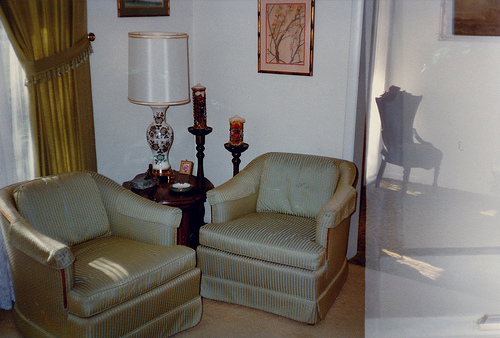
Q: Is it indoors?
A: Yes, it is indoors.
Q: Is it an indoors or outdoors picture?
A: It is indoors.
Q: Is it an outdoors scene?
A: No, it is indoors.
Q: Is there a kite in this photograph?
A: No, there are no kites.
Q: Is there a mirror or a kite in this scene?
A: No, there are no kites or mirrors.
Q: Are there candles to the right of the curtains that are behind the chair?
A: Yes, there is a candle to the right of the curtains.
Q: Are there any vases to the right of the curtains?
A: No, there is a candle to the right of the curtains.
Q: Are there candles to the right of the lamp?
A: Yes, there is a candle to the right of the lamp.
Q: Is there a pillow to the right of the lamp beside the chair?
A: No, there is a candle to the right of the lamp.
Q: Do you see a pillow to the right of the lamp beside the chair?
A: No, there is a candle to the right of the lamp.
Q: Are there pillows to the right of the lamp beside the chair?
A: No, there is a candle to the right of the lamp.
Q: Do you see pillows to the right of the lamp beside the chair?
A: No, there is a candle to the right of the lamp.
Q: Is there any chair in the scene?
A: Yes, there is a chair.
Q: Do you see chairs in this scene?
A: Yes, there is a chair.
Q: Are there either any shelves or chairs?
A: Yes, there is a chair.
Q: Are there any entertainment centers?
A: No, there are no entertainment centers.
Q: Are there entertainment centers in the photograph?
A: No, there are no entertainment centers.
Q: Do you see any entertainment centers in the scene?
A: No, there are no entertainment centers.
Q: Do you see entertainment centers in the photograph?
A: No, there are no entertainment centers.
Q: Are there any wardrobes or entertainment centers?
A: No, there are no entertainment centers or wardrobes.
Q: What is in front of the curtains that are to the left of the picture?
A: The chair is in front of the curtains.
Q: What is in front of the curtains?
A: The chair is in front of the curtains.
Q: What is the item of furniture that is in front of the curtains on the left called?
A: The piece of furniture is a chair.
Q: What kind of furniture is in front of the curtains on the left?
A: The piece of furniture is a chair.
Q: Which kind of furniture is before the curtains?
A: The piece of furniture is a chair.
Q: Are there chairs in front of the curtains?
A: Yes, there is a chair in front of the curtains.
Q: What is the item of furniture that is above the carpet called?
A: The piece of furniture is a chair.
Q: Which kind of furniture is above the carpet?
A: The piece of furniture is a chair.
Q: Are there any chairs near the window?
A: Yes, there is a chair near the window.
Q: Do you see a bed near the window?
A: No, there is a chair near the window.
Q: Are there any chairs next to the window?
A: Yes, there is a chair next to the window.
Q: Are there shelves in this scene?
A: No, there are no shelves.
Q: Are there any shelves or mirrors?
A: No, there are no shelves or mirrors.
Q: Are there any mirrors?
A: No, there are no mirrors.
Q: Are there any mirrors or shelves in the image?
A: No, there are no mirrors or shelves.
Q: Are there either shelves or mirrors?
A: No, there are no mirrors or shelves.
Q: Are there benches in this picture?
A: No, there are no benches.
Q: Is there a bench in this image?
A: No, there are no benches.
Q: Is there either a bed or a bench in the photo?
A: No, there are no benches or beds.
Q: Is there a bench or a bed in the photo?
A: No, there are no benches or beds.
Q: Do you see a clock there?
A: No, there are no clocks.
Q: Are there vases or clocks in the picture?
A: No, there are no clocks or vases.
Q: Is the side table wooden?
A: Yes, the side table is wooden.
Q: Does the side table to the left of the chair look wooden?
A: Yes, the side table is wooden.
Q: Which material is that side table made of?
A: The side table is made of wood.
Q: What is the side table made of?
A: The side table is made of wood.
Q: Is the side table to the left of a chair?
A: Yes, the side table is to the left of a chair.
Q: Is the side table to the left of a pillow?
A: No, the side table is to the left of a chair.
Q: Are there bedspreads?
A: No, there are no bedspreads.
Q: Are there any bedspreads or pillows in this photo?
A: No, there are no bedspreads or pillows.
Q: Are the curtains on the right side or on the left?
A: The curtains are on the left of the image.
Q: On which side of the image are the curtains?
A: The curtains are on the left of the image.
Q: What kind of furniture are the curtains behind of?
A: The curtains are behind the chair.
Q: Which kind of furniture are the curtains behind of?
A: The curtains are behind the chair.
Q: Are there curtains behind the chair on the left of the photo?
A: Yes, there are curtains behind the chair.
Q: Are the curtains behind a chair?
A: Yes, the curtains are behind a chair.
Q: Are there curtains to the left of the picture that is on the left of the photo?
A: Yes, there are curtains to the left of the picture.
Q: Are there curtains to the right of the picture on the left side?
A: No, the curtains are to the left of the picture.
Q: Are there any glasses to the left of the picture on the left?
A: No, there are curtains to the left of the picture.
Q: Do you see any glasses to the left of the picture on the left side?
A: No, there are curtains to the left of the picture.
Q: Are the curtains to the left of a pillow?
A: No, the curtains are to the left of the picture.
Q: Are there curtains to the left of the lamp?
A: Yes, there are curtains to the left of the lamp.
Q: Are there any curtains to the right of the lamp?
A: No, the curtains are to the left of the lamp.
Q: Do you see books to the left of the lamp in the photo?
A: No, there are curtains to the left of the lamp.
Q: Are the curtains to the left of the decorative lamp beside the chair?
A: Yes, the curtains are to the left of the lamp.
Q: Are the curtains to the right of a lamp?
A: No, the curtains are to the left of a lamp.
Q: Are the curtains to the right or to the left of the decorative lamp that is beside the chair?
A: The curtains are to the left of the lamp.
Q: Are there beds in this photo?
A: No, there are no beds.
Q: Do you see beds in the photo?
A: No, there are no beds.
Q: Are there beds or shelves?
A: No, there are no beds or shelves.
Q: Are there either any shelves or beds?
A: No, there are no beds or shelves.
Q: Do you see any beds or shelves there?
A: No, there are no beds or shelves.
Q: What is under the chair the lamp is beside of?
A: The carpet is under the chair.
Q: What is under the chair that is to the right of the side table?
A: The carpet is under the chair.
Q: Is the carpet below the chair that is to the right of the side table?
A: Yes, the carpet is below the chair.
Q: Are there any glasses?
A: No, there are no glasses.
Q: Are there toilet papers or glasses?
A: No, there are no glasses or toilet papers.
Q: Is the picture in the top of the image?
A: Yes, the picture is in the top of the image.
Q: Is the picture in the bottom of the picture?
A: No, the picture is in the top of the image.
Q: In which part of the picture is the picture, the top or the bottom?
A: The picture is in the top of the image.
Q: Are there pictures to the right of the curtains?
A: Yes, there is a picture to the right of the curtains.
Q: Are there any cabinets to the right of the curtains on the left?
A: No, there is a picture to the right of the curtains.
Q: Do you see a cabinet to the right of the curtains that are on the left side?
A: No, there is a picture to the right of the curtains.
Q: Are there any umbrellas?
A: No, there are no umbrellas.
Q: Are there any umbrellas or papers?
A: No, there are no umbrellas or papers.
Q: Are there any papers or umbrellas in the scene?
A: No, there are no umbrellas or papers.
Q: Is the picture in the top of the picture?
A: Yes, the picture is in the top of the image.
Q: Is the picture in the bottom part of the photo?
A: No, the picture is in the top of the image.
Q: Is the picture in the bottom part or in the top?
A: The picture is in the top of the image.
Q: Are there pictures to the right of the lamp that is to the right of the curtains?
A: Yes, there is a picture to the right of the lamp.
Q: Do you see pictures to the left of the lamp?
A: No, the picture is to the right of the lamp.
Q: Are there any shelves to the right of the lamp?
A: No, there is a picture to the right of the lamp.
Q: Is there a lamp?
A: Yes, there is a lamp.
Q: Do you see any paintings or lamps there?
A: Yes, there is a lamp.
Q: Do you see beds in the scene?
A: No, there are no beds.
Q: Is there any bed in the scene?
A: No, there are no beds.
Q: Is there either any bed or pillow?
A: No, there are no beds or pillows.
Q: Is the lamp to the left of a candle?
A: Yes, the lamp is to the left of a candle.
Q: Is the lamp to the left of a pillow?
A: No, the lamp is to the left of a candle.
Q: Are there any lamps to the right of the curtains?
A: Yes, there is a lamp to the right of the curtains.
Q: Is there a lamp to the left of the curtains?
A: No, the lamp is to the right of the curtains.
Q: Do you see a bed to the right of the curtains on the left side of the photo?
A: No, there is a lamp to the right of the curtains.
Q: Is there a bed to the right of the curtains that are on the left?
A: No, there is a lamp to the right of the curtains.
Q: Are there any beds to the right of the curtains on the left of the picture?
A: No, there is a lamp to the right of the curtains.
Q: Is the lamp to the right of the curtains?
A: Yes, the lamp is to the right of the curtains.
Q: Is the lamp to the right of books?
A: No, the lamp is to the right of the curtains.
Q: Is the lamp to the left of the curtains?
A: No, the lamp is to the right of the curtains.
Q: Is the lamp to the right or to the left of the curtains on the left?
A: The lamp is to the right of the curtains.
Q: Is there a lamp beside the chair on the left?
A: Yes, there is a lamp beside the chair.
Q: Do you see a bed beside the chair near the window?
A: No, there is a lamp beside the chair.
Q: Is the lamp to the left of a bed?
A: No, the lamp is to the left of a candle.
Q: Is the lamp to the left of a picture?
A: Yes, the lamp is to the left of a picture.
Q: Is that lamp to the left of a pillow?
A: No, the lamp is to the left of a picture.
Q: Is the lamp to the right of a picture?
A: No, the lamp is to the left of a picture.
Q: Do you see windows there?
A: Yes, there is a window.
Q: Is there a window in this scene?
A: Yes, there is a window.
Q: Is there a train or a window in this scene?
A: Yes, there is a window.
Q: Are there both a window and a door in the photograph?
A: No, there is a window but no doors.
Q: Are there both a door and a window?
A: No, there is a window but no doors.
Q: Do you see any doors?
A: No, there are no doors.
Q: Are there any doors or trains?
A: No, there are no doors or trains.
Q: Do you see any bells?
A: No, there are no bells.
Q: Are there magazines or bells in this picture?
A: No, there are no bells or magazines.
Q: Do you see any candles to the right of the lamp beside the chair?
A: Yes, there is a candle to the right of the lamp.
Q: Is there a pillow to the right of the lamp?
A: No, there is a candle to the right of the lamp.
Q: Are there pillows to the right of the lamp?
A: No, there is a candle to the right of the lamp.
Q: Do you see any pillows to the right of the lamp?
A: No, there is a candle to the right of the lamp.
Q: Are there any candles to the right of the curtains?
A: Yes, there is a candle to the right of the curtains.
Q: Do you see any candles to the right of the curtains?
A: Yes, there is a candle to the right of the curtains.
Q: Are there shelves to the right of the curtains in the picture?
A: No, there is a candle to the right of the curtains.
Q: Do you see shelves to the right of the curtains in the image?
A: No, there is a candle to the right of the curtains.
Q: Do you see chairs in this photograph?
A: Yes, there is a chair.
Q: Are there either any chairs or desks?
A: Yes, there is a chair.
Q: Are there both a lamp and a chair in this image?
A: Yes, there are both a chair and a lamp.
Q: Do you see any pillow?
A: No, there are no pillows.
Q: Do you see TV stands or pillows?
A: No, there are no pillows or TV stands.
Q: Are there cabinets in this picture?
A: No, there are no cabinets.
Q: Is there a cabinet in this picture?
A: No, there are no cabinets.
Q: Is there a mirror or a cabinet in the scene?
A: No, there are no cabinets or mirrors.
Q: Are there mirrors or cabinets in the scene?
A: No, there are no cabinets or mirrors.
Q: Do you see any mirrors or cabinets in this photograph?
A: No, there are no cabinets or mirrors.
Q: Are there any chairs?
A: Yes, there is a chair.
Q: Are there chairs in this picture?
A: Yes, there is a chair.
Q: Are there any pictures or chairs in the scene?
A: Yes, there is a chair.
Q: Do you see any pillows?
A: No, there are no pillows.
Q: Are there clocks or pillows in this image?
A: No, there are no pillows or clocks.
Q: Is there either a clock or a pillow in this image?
A: No, there are no pillows or clocks.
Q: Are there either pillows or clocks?
A: No, there are no pillows or clocks.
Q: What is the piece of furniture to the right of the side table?
A: The piece of furniture is a chair.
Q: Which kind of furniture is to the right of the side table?
A: The piece of furniture is a chair.